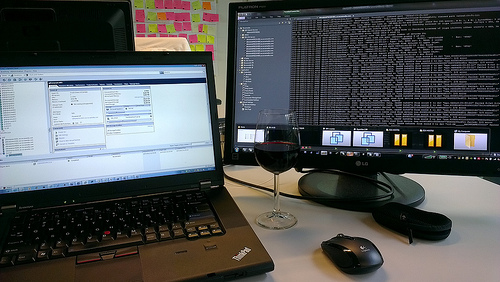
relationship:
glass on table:
[254, 107, 301, 229] [217, 160, 498, 280]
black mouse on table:
[319, 234, 385, 274] [217, 160, 498, 280]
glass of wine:
[254, 107, 301, 229] [251, 139, 298, 173]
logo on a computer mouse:
[355, 242, 379, 259] [317, 224, 394, 274]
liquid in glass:
[248, 147, 300, 172] [248, 111, 316, 238]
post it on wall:
[131, 9, 148, 24] [133, 0, 222, 52]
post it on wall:
[145, 9, 155, 23] [133, 0, 222, 52]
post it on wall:
[154, 8, 167, 22] [133, 0, 222, 52]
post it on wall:
[175, 8, 184, 22] [133, 0, 222, 52]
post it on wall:
[183, 11, 189, 21] [133, 0, 222, 52]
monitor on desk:
[226, 0, 499, 173] [258, 178, 496, 280]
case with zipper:
[367, 195, 469, 255] [370, 207, 455, 234]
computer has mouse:
[2, 6, 222, 272] [314, 225, 392, 271]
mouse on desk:
[314, 225, 392, 271] [220, 157, 497, 279]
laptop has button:
[0, 51, 276, 280] [168, 218, 185, 231]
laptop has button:
[0, 51, 276, 280] [199, 225, 211, 237]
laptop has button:
[0, 51, 276, 280] [113, 228, 128, 238]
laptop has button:
[0, 51, 276, 280] [144, 223, 156, 235]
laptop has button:
[0, 51, 276, 280] [136, 206, 146, 218]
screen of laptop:
[2, 43, 233, 198] [0, 51, 276, 280]